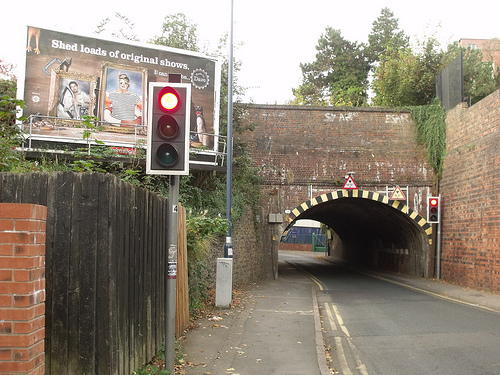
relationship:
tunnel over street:
[236, 126, 467, 275] [303, 258, 499, 375]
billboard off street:
[25, 26, 225, 153] [303, 258, 499, 375]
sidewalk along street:
[248, 261, 310, 371] [303, 258, 499, 375]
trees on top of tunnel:
[294, 32, 453, 106] [236, 126, 467, 275]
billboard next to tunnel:
[25, 26, 225, 153] [236, 126, 467, 275]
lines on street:
[324, 299, 362, 373] [303, 258, 499, 375]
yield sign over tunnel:
[341, 175, 355, 187] [236, 126, 467, 275]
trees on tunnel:
[294, 32, 453, 106] [236, 126, 467, 275]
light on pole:
[162, 90, 182, 115] [167, 179, 176, 354]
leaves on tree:
[395, 77, 425, 97] [380, 38, 431, 113]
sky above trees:
[3, 0, 499, 96] [294, 32, 453, 106]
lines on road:
[324, 299, 362, 373] [303, 258, 499, 375]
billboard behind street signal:
[25, 26, 225, 153] [153, 79, 187, 172]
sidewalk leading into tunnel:
[248, 261, 310, 371] [236, 126, 467, 275]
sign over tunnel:
[341, 175, 355, 187] [236, 126, 467, 275]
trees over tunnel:
[294, 32, 453, 106] [236, 126, 467, 275]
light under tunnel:
[161, 92, 179, 110] [236, 126, 467, 275]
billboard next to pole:
[25, 26, 225, 153] [224, 4, 233, 332]